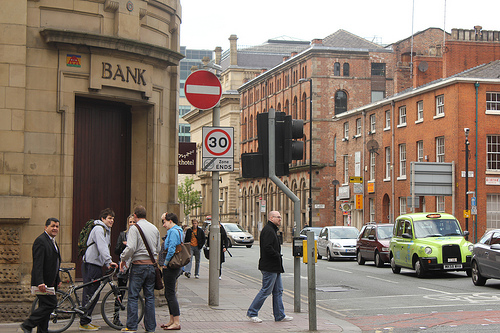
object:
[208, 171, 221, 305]
pole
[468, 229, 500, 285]
cars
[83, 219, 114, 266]
hoodie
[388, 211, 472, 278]
cab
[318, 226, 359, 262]
silver sedan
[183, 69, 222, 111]
sign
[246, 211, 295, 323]
man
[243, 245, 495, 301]
road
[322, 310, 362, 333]
curb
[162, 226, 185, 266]
blue jacket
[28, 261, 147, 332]
bicycle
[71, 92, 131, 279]
door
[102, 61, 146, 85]
bank sign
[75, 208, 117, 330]
man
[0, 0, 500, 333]
street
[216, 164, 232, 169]
writing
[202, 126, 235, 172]
sign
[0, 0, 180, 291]
bank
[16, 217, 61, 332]
man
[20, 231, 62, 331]
suit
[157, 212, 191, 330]
lady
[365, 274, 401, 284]
lines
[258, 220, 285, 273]
jacket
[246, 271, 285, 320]
pants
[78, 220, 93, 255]
backpack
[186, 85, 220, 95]
bar